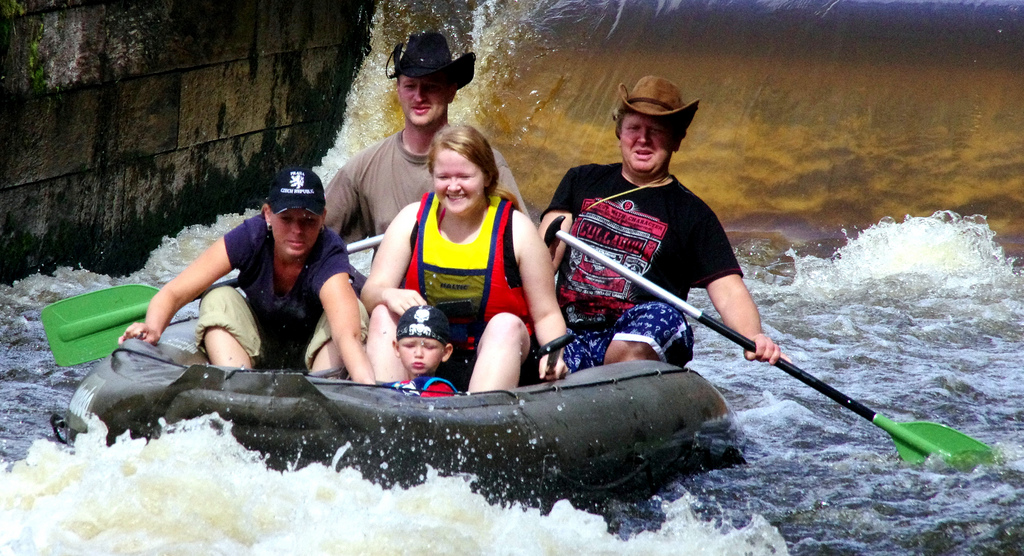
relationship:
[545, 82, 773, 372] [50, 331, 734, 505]
man in raft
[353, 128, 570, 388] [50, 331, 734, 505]
person in raft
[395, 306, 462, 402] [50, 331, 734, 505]
child in raft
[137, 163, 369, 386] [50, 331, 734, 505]
person in raft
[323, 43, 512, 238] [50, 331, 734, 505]
man in raft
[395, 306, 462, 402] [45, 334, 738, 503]
child riding boat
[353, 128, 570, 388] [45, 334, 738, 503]
person riding boat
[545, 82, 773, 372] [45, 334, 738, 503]
man riding boat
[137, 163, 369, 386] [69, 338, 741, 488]
person in raft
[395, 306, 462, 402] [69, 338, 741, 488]
child in raft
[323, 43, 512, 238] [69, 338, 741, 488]
man in raft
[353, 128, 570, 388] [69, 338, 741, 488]
person in raft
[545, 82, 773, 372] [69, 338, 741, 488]
man in raft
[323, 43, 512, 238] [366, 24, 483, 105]
man wearing cowboy hat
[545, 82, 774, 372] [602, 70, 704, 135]
man wearing cowboy hat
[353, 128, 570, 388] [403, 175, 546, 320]
person wearing flotation vest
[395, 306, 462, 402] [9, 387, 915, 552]
child looking at water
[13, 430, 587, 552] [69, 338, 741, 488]
wave hitting raft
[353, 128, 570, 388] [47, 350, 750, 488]
person sitting in raft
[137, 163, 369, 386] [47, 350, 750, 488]
person sitting in raft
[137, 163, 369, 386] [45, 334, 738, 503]
person riding boat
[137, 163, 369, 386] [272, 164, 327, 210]
person wearing cap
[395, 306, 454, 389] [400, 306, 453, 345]
child wearing cap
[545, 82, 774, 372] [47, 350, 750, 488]
man paddling raft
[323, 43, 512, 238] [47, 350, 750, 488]
man paddling raft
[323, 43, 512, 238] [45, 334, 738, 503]
man on boat